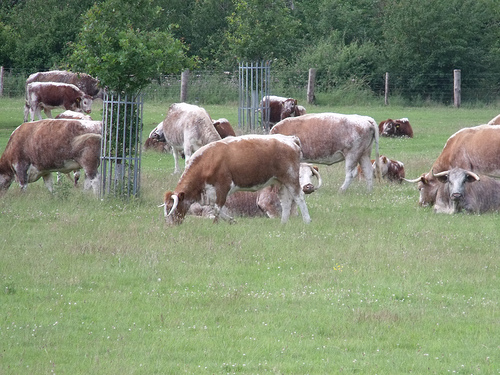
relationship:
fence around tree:
[99, 89, 144, 202] [67, 21, 191, 205]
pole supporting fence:
[452, 69, 464, 108] [145, 65, 500, 110]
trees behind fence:
[1, 1, 500, 76] [145, 65, 500, 110]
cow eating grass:
[157, 133, 314, 229] [0, 97, 499, 374]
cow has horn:
[157, 133, 314, 229] [169, 194, 178, 216]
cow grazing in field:
[398, 122, 498, 207] [1, 97, 500, 370]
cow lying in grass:
[378, 117, 414, 138] [0, 97, 499, 374]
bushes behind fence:
[276, 21, 414, 106] [145, 65, 500, 110]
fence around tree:
[235, 60, 281, 133] [226, 0, 305, 135]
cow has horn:
[432, 126, 499, 199] [465, 171, 482, 183]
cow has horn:
[432, 126, 499, 199] [432, 169, 451, 178]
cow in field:
[398, 122, 498, 207] [1, 97, 500, 370]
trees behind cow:
[1, 1, 500, 76] [398, 122, 498, 207]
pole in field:
[180, 69, 189, 101] [1, 97, 500, 370]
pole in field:
[306, 67, 317, 103] [1, 97, 500, 370]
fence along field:
[145, 65, 500, 110] [1, 97, 500, 370]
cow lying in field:
[378, 117, 414, 138] [1, 97, 500, 370]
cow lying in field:
[199, 163, 324, 224] [1, 97, 500, 370]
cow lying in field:
[370, 155, 406, 184] [1, 97, 500, 370]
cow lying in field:
[418, 167, 500, 214] [1, 97, 500, 370]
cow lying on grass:
[378, 117, 414, 138] [0, 97, 499, 374]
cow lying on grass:
[370, 155, 406, 184] [0, 97, 499, 374]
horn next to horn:
[465, 171, 482, 183] [432, 169, 451, 178]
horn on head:
[465, 171, 482, 183] [436, 167, 479, 199]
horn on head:
[432, 169, 451, 178] [436, 167, 479, 199]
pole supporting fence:
[180, 69, 189, 101] [145, 65, 500, 110]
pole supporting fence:
[306, 67, 317, 103] [145, 65, 500, 110]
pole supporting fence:
[385, 72, 393, 106] [145, 65, 500, 110]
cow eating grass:
[25, 82, 93, 120] [0, 97, 499, 374]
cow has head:
[157, 133, 314, 229] [158, 192, 192, 226]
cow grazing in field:
[25, 69, 104, 100] [1, 97, 500, 370]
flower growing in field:
[31, 326, 36, 333] [1, 97, 500, 370]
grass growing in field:
[0, 97, 499, 374] [1, 97, 500, 370]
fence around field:
[145, 65, 500, 110] [1, 97, 500, 370]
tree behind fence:
[67, 21, 191, 205] [99, 89, 144, 202]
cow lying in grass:
[199, 163, 324, 224] [0, 97, 499, 374]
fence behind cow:
[145, 65, 500, 110] [398, 122, 498, 207]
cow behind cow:
[378, 117, 414, 138] [398, 122, 498, 207]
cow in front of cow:
[25, 82, 93, 120] [25, 69, 104, 100]